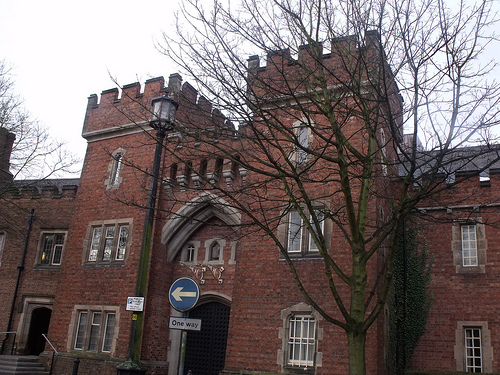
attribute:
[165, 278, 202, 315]
sign — blue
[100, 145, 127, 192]
window — arched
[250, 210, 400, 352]
building — brick, gothic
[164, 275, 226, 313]
sign — blue, white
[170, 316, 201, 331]
sign — one way sign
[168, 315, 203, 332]
sign — one way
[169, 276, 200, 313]
blue/white sign — blue, white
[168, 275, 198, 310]
sign — one way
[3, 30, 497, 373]
building — brick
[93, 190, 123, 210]
brick — red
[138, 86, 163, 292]
lamp post — tall, black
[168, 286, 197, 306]
arrow — white